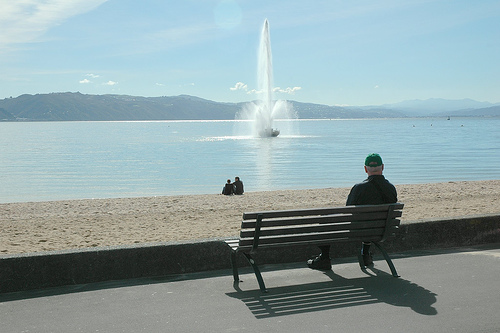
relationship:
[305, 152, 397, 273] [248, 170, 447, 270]
man on bench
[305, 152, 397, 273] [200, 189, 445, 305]
man on bench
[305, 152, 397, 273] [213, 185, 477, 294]
man on bench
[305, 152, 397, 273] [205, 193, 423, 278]
man on bench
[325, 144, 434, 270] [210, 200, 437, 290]
man on bench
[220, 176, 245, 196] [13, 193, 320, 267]
couple on sand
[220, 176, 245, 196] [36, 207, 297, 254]
couple on sand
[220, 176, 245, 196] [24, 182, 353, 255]
couple on sand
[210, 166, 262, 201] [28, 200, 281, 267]
couple on sand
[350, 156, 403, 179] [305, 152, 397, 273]
head on man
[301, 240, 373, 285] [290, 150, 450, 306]
foot on person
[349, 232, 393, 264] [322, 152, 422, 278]
foot on person